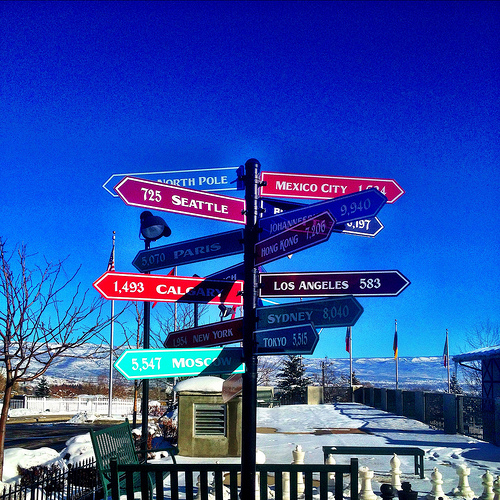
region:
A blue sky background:
[8, 24, 203, 116]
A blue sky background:
[208, 20, 345, 104]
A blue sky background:
[411, 25, 498, 123]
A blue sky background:
[417, 155, 498, 345]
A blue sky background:
[5, 153, 119, 328]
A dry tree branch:
[2, 257, 82, 462]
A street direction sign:
[118, 178, 243, 220]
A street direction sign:
[98, 280, 249, 304]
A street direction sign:
[104, 345, 252, 380]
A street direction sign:
[261, 273, 411, 301]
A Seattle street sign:
[115, 175, 250, 221]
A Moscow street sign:
[114, 341, 247, 374]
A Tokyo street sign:
[257, 323, 317, 353]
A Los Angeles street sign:
[259, 271, 409, 296]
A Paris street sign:
[132, 230, 247, 267]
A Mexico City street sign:
[260, 170, 404, 203]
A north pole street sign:
[103, 169, 244, 195]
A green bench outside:
[92, 416, 178, 492]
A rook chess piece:
[357, 469, 376, 499]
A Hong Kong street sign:
[252, 213, 333, 266]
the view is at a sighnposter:
[150, 140, 364, 415]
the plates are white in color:
[414, 463, 498, 490]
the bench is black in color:
[143, 458, 215, 498]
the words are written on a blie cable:
[263, 330, 329, 354]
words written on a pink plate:
[133, 173, 230, 214]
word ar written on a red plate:
[276, 172, 345, 197]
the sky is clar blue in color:
[411, 121, 461, 198]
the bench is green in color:
[94, 430, 145, 460]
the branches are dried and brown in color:
[18, 292, 91, 365]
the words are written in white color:
[121, 275, 230, 304]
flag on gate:
[441, 325, 451, 388]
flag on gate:
[390, 317, 403, 392]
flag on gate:
[341, 328, 357, 386]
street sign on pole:
[111, 346, 246, 377]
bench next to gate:
[86, 430, 151, 495]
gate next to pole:
[238, 158, 258, 499]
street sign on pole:
[93, 273, 248, 308]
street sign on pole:
[118, 178, 248, 222]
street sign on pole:
[258, 169, 403, 201]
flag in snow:
[103, 231, 120, 421]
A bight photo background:
[111, 353, 245, 374]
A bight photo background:
[87, 257, 247, 311]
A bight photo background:
[114, 178, 252, 230]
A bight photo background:
[255, 271, 406, 296]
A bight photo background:
[250, 298, 362, 332]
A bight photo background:
[264, 154, 401, 201]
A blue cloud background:
[407, 210, 485, 354]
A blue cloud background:
[25, 97, 112, 234]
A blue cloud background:
[94, 25, 328, 145]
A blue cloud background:
[367, 10, 498, 174]